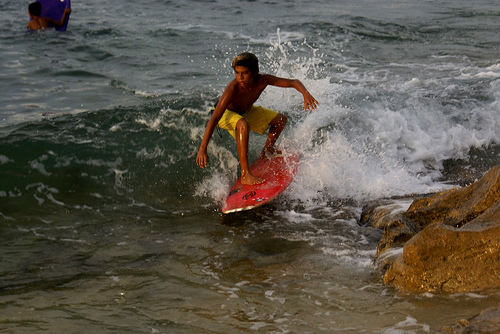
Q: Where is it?
A: This is at the ocean.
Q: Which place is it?
A: It is an ocean.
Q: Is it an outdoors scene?
A: Yes, it is outdoors.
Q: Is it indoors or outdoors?
A: It is outdoors.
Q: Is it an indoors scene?
A: No, it is outdoors.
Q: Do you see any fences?
A: No, there are no fences.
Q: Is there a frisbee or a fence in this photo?
A: No, there are no fences or frisbees.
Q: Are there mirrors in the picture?
A: No, there are no mirrors.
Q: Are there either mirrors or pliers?
A: No, there are no mirrors or pliers.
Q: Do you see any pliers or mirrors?
A: No, there are no mirrors or pliers.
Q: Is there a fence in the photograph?
A: No, there are no fences.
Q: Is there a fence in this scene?
A: No, there are no fences.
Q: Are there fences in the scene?
A: No, there are no fences.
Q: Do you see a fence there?
A: No, there are no fences.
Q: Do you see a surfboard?
A: Yes, there is a surfboard.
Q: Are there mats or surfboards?
A: Yes, there is a surfboard.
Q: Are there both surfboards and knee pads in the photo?
A: No, there is a surfboard but no knee pads.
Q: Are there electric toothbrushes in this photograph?
A: No, there are no electric toothbrushes.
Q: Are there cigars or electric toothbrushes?
A: No, there are no electric toothbrushes or cigars.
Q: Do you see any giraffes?
A: No, there are no giraffes.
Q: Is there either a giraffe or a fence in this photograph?
A: No, there are no giraffes or fences.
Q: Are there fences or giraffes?
A: No, there are no giraffes or fences.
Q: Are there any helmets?
A: No, there are no helmets.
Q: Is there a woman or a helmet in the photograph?
A: No, there are no helmets or women.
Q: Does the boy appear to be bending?
A: Yes, the boy is bending.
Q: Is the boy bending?
A: Yes, the boy is bending.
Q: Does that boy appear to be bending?
A: Yes, the boy is bending.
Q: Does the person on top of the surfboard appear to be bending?
A: Yes, the boy is bending.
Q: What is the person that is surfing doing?
A: The boy is bending.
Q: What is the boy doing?
A: The boy is bending.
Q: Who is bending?
A: The boy is bending.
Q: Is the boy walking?
A: No, the boy is bending.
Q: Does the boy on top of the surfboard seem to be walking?
A: No, the boy is bending.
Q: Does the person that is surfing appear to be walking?
A: No, the boy is bending.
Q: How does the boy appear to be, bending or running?
A: The boy is bending.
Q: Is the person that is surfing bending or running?
A: The boy is bending.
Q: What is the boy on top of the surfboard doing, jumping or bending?
A: The boy is bending.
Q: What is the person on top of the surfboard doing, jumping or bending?
A: The boy is bending.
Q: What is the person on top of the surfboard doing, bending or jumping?
A: The boy is bending.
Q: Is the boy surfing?
A: Yes, the boy is surfing.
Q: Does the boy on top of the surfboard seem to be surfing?
A: Yes, the boy is surfing.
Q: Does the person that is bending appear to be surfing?
A: Yes, the boy is surfing.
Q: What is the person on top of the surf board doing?
A: The boy is surfing.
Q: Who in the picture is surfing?
A: The boy is surfing.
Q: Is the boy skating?
A: No, the boy is surfing.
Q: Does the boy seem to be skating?
A: No, the boy is surfing.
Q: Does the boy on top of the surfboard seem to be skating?
A: No, the boy is surfing.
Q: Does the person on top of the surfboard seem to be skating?
A: No, the boy is surfing.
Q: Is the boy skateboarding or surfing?
A: The boy is surfing.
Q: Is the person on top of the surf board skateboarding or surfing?
A: The boy is surfing.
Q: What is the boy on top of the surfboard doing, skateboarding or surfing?
A: The boy is surfing.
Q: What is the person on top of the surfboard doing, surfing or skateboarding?
A: The boy is surfing.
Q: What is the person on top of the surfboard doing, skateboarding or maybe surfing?
A: The boy is surfing.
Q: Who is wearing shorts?
A: The boy is wearing shorts.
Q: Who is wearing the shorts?
A: The boy is wearing shorts.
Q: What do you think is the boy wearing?
A: The boy is wearing shorts.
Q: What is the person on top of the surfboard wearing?
A: The boy is wearing shorts.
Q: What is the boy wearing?
A: The boy is wearing shorts.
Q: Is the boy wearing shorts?
A: Yes, the boy is wearing shorts.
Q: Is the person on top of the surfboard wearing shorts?
A: Yes, the boy is wearing shorts.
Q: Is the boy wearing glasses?
A: No, the boy is wearing shorts.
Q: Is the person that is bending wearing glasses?
A: No, the boy is wearing shorts.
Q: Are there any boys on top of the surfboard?
A: Yes, there is a boy on top of the surfboard.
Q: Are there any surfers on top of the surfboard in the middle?
A: No, there is a boy on top of the surfboard.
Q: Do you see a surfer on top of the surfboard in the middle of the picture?
A: No, there is a boy on top of the surfboard.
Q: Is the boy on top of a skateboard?
A: No, the boy is on top of the surfboard.